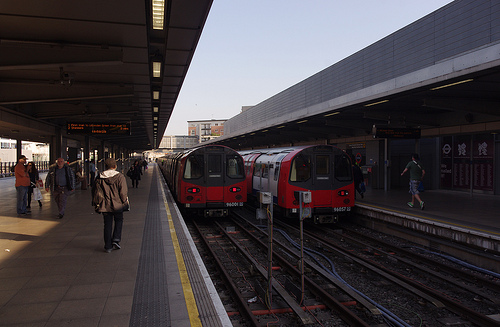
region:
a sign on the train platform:
[65, 120, 132, 135]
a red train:
[155, 135, 245, 210]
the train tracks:
[200, 205, 470, 320]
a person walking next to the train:
[391, 141, 436, 206]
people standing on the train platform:
[10, 150, 125, 221]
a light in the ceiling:
[147, 60, 162, 80]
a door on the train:
[205, 150, 220, 197]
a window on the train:
[225, 157, 236, 172]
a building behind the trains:
[170, 115, 215, 132]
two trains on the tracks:
[146, 135, 452, 305]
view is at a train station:
[106, 122, 361, 282]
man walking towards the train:
[63, 159, 173, 254]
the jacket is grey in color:
[86, 175, 143, 206]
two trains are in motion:
[176, 127, 386, 243]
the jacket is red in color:
[3, 157, 27, 186]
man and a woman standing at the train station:
[11, 156, 43, 209]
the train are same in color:
[176, 130, 338, 225]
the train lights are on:
[176, 182, 258, 201]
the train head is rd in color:
[175, 151, 287, 197]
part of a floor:
[126, 235, 164, 285]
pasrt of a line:
[175, 265, 210, 320]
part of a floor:
[99, 263, 128, 291]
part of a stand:
[283, 216, 323, 315]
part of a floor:
[120, 267, 140, 284]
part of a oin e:
[170, 250, 197, 315]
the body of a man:
[76, 139, 133, 243]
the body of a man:
[67, 141, 165, 278]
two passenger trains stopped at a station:
[136, 118, 371, 250]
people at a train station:
[13, 139, 156, 256]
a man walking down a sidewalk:
[91, 155, 152, 262]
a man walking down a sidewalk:
[46, 152, 75, 215]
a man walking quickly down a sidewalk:
[398, 150, 442, 215]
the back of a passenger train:
[167, 135, 255, 220]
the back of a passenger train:
[286, 141, 361, 230]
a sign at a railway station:
[59, 116, 135, 140]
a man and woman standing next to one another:
[2, 148, 43, 221]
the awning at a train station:
[10, 63, 183, 146]